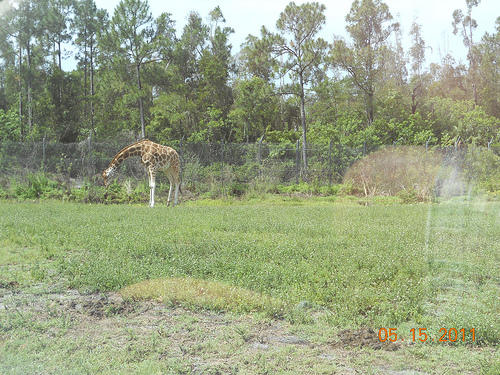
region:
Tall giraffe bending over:
[106, 122, 200, 195]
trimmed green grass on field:
[11, 205, 428, 372]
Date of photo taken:
[368, 322, 493, 362]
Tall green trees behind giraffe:
[2, 0, 498, 186]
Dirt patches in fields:
[83, 292, 267, 372]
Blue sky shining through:
[15, 5, 497, 107]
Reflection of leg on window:
[315, 125, 495, 257]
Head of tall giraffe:
[93, 166, 120, 190]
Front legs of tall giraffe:
[141, 172, 156, 201]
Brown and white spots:
[129, 143, 151, 153]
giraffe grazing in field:
[97, 133, 191, 211]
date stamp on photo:
[373, 323, 478, 349]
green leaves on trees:
[174, 21, 240, 116]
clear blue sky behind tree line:
[230, 11, 316, 46]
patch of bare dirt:
[47, 294, 280, 353]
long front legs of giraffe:
[144, 168, 160, 210]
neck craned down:
[111, 144, 143, 171]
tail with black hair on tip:
[174, 170, 186, 198]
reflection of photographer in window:
[423, 158, 486, 326]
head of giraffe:
[98, 167, 116, 192]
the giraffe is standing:
[113, 135, 201, 215]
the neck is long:
[105, 144, 175, 175]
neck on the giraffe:
[90, 142, 195, 207]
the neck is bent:
[97, 145, 211, 185]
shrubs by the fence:
[21, 145, 141, 208]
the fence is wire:
[213, 145, 339, 197]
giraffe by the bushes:
[90, 140, 214, 210]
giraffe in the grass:
[97, 134, 214, 236]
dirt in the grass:
[70, 274, 270, 354]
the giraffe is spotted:
[88, 139, 223, 215]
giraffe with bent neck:
[97, 129, 187, 218]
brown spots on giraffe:
[147, 144, 173, 167]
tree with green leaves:
[272, 6, 327, 90]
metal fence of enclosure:
[248, 133, 340, 191]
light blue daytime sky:
[407, 4, 463, 44]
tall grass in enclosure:
[187, 220, 297, 265]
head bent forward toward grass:
[97, 159, 123, 198]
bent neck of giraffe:
[112, 140, 148, 170]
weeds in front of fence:
[17, 170, 102, 201]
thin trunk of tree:
[298, 114, 314, 176]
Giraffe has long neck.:
[97, 138, 136, 172]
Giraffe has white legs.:
[143, 187, 231, 221]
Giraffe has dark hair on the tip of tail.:
[176, 176, 188, 198]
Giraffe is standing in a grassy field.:
[136, 184, 198, 215]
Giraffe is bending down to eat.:
[91, 137, 140, 227]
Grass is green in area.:
[198, 222, 373, 322]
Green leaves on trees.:
[256, 106, 373, 152]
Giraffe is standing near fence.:
[28, 134, 228, 216]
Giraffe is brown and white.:
[86, 109, 223, 246]